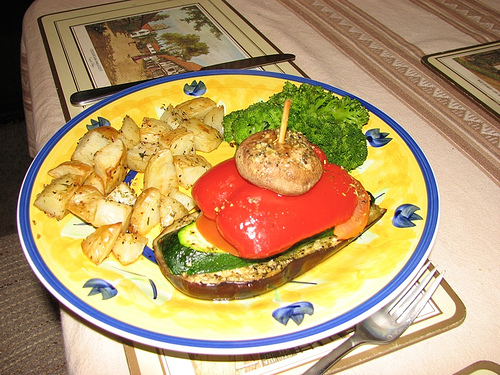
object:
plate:
[16, 69, 440, 356]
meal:
[34, 83, 387, 301]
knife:
[69, 53, 296, 109]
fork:
[302, 258, 446, 374]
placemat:
[37, 0, 309, 125]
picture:
[69, 4, 261, 92]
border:
[19, 68, 438, 351]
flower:
[182, 79, 207, 97]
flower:
[363, 127, 391, 149]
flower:
[392, 203, 423, 230]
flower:
[271, 302, 316, 327]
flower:
[82, 277, 119, 302]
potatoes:
[80, 221, 123, 265]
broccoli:
[222, 81, 371, 173]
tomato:
[332, 178, 369, 243]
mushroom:
[234, 128, 321, 196]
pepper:
[192, 144, 358, 261]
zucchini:
[157, 219, 335, 278]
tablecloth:
[22, 0, 499, 374]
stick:
[278, 98, 294, 148]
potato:
[176, 97, 214, 123]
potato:
[144, 150, 179, 198]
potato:
[34, 173, 80, 221]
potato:
[92, 139, 129, 198]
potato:
[139, 119, 172, 145]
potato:
[71, 122, 119, 165]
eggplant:
[152, 203, 387, 300]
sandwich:
[154, 129, 388, 303]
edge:
[154, 240, 349, 299]